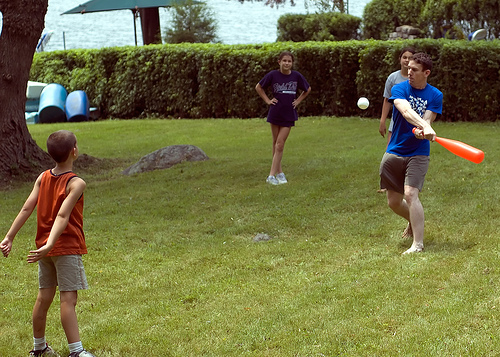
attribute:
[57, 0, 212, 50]
umbrella — green 